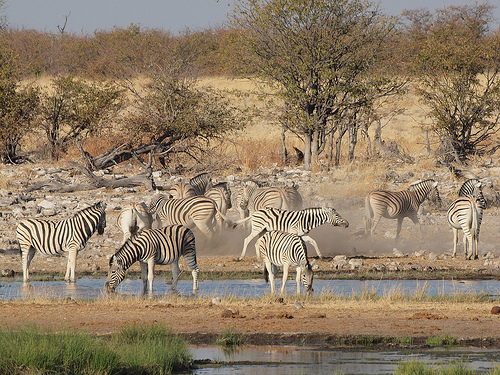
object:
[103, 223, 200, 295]
zebra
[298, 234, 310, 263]
mane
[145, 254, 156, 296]
leg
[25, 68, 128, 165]
tree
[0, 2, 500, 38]
sky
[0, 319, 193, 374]
grass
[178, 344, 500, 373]
stream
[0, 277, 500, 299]
stream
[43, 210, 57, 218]
rocks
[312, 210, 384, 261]
dust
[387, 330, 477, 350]
grass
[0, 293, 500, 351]
stream shore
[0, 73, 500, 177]
grass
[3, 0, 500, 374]
field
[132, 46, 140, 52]
leaves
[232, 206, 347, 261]
zebra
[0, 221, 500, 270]
shore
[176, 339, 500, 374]
pond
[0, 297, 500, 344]
ground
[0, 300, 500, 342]
dirt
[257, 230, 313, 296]
zebra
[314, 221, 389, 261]
dust cloud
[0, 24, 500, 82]
trees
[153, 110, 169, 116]
leaves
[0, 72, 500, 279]
ground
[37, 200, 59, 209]
rocks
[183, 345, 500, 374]
ripples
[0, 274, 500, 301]
water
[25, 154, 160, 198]
log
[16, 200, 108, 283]
zebra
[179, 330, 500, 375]
muddy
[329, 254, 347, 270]
rocks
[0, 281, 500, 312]
grass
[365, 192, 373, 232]
tail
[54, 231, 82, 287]
two